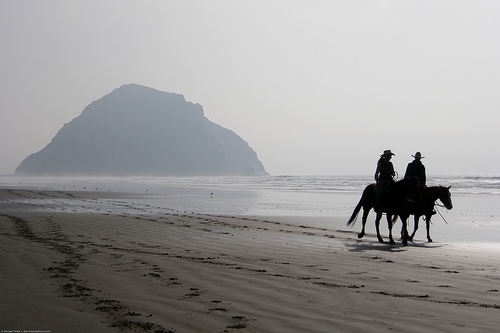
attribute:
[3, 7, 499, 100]
sky — white, gray, cloudy, grey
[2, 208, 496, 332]
beach — sandy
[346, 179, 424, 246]
horse — walking, black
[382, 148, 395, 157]
hat — dark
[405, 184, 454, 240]
horse — walking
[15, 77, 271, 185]
hill — foggy, small, tall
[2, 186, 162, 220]
sand — wet, gray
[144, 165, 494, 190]
water — calm, body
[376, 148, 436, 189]
couple — riding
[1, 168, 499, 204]
sea — gray